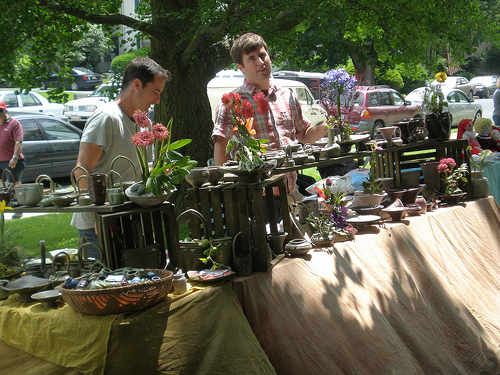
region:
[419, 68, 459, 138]
a red flower in a black jar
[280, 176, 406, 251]
small pottery on a tabletop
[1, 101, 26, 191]
a man in an orange hat and brown shirt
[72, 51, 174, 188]
a guy wearing a gray shirt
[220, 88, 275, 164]
a collection of red roses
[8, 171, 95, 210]
teapots on a countertop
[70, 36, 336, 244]
two guys looking at merchandise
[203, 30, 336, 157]
Man in short sleeved shirt is staring at the camera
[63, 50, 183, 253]
Man in shirt is looking at the items for sale`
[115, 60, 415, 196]
Different types of flowers are on display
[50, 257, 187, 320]
Basket of items sits on the corner of the table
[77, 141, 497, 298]
Wooden crates hold up the shelves of pottery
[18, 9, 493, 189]
Large oak tree provides plenty of shade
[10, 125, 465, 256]
Different sizes pottery are on display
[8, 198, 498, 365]
Tables are covered with various sheets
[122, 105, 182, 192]
flowers in a pot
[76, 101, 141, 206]
man wearing a gray shirt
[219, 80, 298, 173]
man wearing a plaid shirt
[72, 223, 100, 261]
man wearing blue jeans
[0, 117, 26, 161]
man wearing a red shirt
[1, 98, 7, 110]
man wearing a red hat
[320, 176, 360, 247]
purple flowers on the table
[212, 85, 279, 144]
red flowers on the table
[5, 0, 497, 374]
a scene during the day time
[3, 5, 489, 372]
a scene of a yard sale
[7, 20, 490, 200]
a parking lot of vehicles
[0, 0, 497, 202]
a tree with green leaves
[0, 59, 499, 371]
tables of random items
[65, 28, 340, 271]
a couple of men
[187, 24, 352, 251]
a man looking at the camera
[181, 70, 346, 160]
a white van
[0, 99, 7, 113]
The red hat on the man's head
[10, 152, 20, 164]
The watch on the man's wrist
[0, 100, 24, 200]
The man wearing a maroon shirt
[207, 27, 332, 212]
The man wearing a plaid shirt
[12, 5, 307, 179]
a tree in a field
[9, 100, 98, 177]
a car in a parking lot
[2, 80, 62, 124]
a car in a parking lot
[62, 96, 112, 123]
a car in a parking lot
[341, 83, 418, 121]
a car in a parking lot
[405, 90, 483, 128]
a car in a parking lot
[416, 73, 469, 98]
a car in a parking lot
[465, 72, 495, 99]
a car in a parking lot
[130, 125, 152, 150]
right small pink flower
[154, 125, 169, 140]
left small pink flower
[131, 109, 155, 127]
small pink flower top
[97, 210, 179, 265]
Right wood box median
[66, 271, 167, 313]
Embroidered small wooden basket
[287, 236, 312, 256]
Small brown ceramic vase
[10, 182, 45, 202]
Small grey ceramic vase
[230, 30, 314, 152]
Man with red plaid shirt and black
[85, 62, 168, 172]
Man with shirt grey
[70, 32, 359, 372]
two men standing at table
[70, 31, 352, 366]
two men standing behind table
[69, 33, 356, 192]
two men standing behind flowers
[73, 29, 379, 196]
two men standing behind three sets of flowers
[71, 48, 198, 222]
man standing behind pink flowers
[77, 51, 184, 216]
Man wearing t-shirt behind flowers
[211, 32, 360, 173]
man standing behind red and purple flowers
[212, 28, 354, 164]
man in dress shirt behind flowers